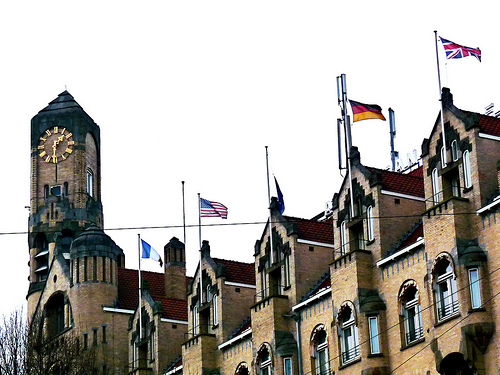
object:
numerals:
[63, 144, 77, 156]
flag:
[197, 190, 229, 245]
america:
[196, 197, 230, 223]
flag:
[343, 97, 387, 149]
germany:
[350, 99, 386, 125]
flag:
[432, 30, 484, 86]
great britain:
[437, 34, 483, 61]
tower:
[29, 90, 105, 238]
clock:
[35, 124, 77, 164]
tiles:
[118, 266, 193, 317]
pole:
[265, 141, 274, 263]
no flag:
[262, 144, 291, 173]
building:
[26, 91, 188, 375]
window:
[425, 250, 464, 327]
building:
[419, 86, 500, 372]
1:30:
[50, 128, 68, 164]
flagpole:
[197, 192, 202, 256]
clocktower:
[25, 91, 105, 271]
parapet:
[21, 227, 69, 280]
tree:
[0, 304, 99, 375]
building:
[180, 238, 260, 374]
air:
[0, 0, 500, 334]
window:
[336, 300, 362, 366]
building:
[329, 146, 399, 374]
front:
[26, 147, 87, 279]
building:
[249, 194, 335, 374]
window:
[35, 288, 81, 341]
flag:
[132, 233, 151, 262]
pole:
[137, 232, 142, 307]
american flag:
[138, 239, 164, 269]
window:
[39, 270, 50, 282]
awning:
[33, 263, 53, 275]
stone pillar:
[31, 83, 102, 158]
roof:
[31, 86, 102, 142]